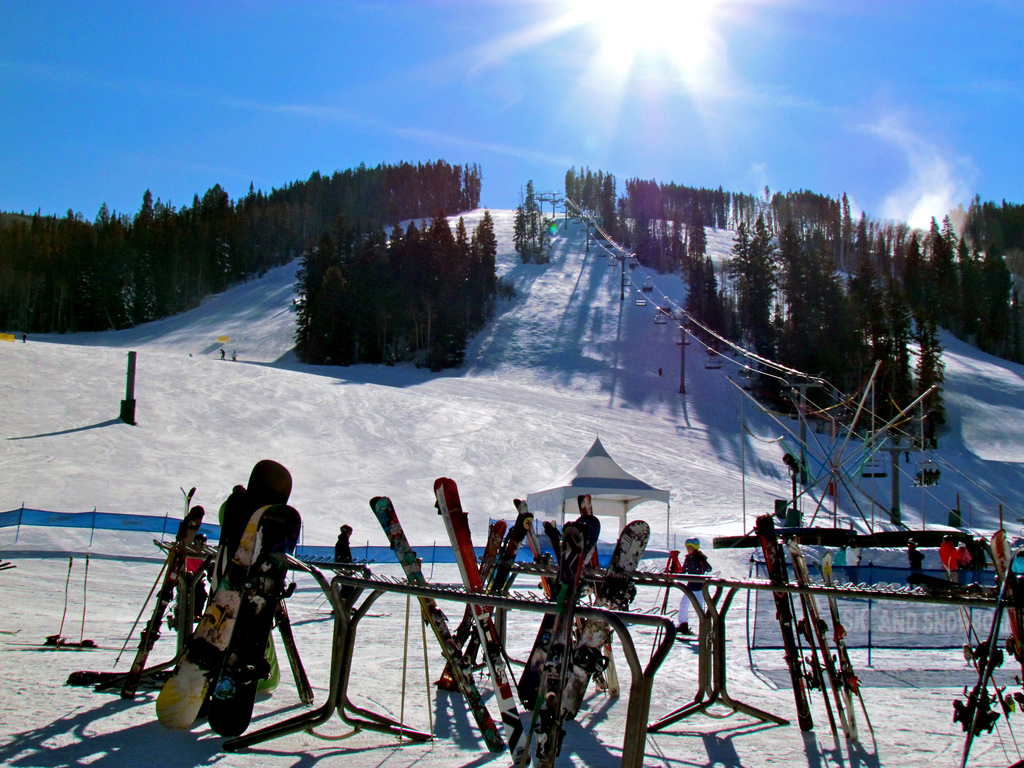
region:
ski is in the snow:
[376, 501, 506, 754]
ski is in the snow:
[433, 476, 522, 721]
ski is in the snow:
[159, 505, 287, 721]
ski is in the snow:
[796, 553, 854, 765]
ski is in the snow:
[822, 559, 883, 765]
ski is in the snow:
[959, 561, 1011, 765]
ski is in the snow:
[550, 517, 656, 765]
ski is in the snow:
[434, 517, 532, 714]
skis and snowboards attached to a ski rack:
[327, 478, 675, 767]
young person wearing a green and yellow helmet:
[675, 535, 711, 637]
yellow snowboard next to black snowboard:
[150, 505, 307, 740]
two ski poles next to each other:
[39, 550, 100, 650]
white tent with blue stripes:
[523, 433, 672, 563]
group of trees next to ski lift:
[537, 167, 1022, 535]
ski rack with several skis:
[704, 513, 1022, 766]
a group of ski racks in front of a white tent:
[153, 434, 1023, 764]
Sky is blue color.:
[38, 30, 450, 149]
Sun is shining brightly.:
[498, 2, 775, 121]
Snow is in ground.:
[43, 328, 748, 733]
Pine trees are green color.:
[27, 151, 991, 453]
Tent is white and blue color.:
[531, 426, 683, 581]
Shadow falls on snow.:
[136, 188, 754, 449]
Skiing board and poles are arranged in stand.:
[119, 472, 976, 767]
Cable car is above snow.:
[541, 184, 950, 514]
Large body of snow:
[347, 391, 453, 458]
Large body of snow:
[195, 375, 307, 434]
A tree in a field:
[512, 209, 526, 247]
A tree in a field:
[319, 260, 351, 368]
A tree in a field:
[324, 207, 357, 269]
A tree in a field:
[319, 226, 335, 264]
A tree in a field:
[297, 231, 323, 339]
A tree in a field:
[435, 263, 471, 355]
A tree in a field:
[462, 228, 489, 315]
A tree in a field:
[482, 216, 503, 311]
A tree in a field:
[454, 226, 468, 264]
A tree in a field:
[701, 254, 728, 338]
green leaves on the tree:
[210, 206, 242, 252]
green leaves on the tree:
[321, 291, 335, 308]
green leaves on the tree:
[327, 268, 373, 320]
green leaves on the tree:
[394, 250, 426, 296]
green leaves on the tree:
[400, 224, 435, 279]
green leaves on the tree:
[778, 276, 830, 384]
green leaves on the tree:
[813, 347, 845, 387]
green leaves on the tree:
[904, 227, 1003, 335]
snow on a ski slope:
[260, 193, 824, 415]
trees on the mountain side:
[49, 154, 996, 420]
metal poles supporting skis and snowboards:
[138, 462, 688, 735]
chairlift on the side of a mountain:
[545, 183, 834, 428]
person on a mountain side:
[658, 356, 675, 379]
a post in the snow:
[114, 350, 146, 431]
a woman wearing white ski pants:
[680, 538, 715, 619]